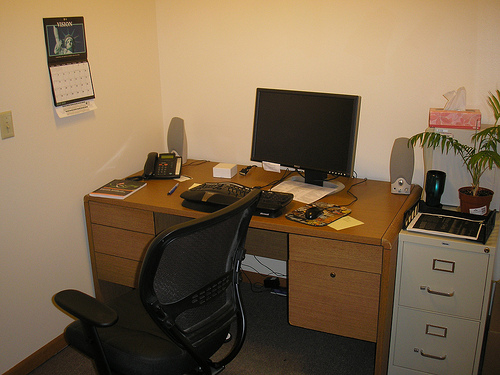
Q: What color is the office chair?
A: Black.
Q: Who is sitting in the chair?
A: No one.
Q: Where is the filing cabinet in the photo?
A: Right side.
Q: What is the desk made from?
A: Wood.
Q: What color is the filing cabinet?
A: Grey.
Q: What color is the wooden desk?
A: Brown.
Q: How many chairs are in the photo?
A: One.